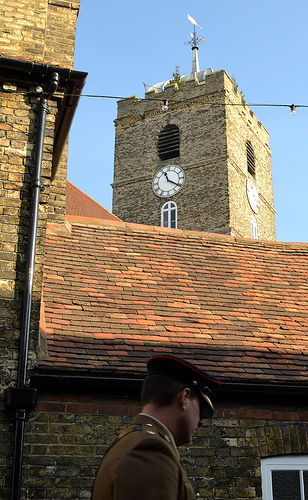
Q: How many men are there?
A: One.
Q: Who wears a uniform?
A: The man.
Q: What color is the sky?
A: Blue.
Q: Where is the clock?
A: In the tower.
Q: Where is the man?
A: In front of the building.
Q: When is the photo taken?
A: In the daytime.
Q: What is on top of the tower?
A: A weathervane.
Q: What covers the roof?
A: Shingles.